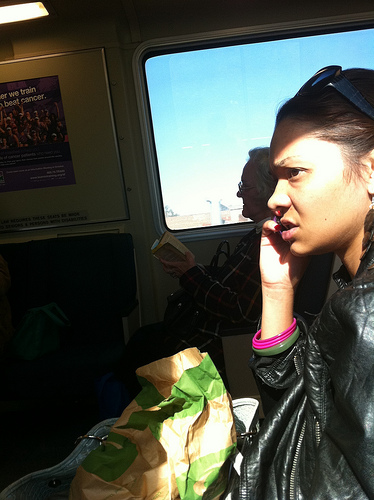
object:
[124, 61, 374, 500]
woman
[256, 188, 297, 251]
phone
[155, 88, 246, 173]
sun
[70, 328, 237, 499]
bag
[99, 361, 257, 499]
lap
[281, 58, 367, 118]
glasses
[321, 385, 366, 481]
black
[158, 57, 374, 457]
people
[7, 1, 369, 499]
train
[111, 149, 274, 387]
woman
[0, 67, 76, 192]
advertisement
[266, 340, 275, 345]
pink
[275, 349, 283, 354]
green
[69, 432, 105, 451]
clasp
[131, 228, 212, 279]
book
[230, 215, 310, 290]
hand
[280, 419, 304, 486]
zippers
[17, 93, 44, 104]
cancer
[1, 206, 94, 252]
row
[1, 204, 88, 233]
black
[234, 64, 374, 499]
lady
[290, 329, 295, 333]
purple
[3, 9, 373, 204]
background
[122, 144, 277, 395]
man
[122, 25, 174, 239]
edge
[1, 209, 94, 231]
lettering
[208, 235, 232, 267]
leather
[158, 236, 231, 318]
purse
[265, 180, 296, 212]
nose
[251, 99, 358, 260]
face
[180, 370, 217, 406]
green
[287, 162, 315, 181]
eye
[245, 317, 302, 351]
bracelets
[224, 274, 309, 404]
arm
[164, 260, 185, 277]
hands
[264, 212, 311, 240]
mouth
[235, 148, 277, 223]
profile